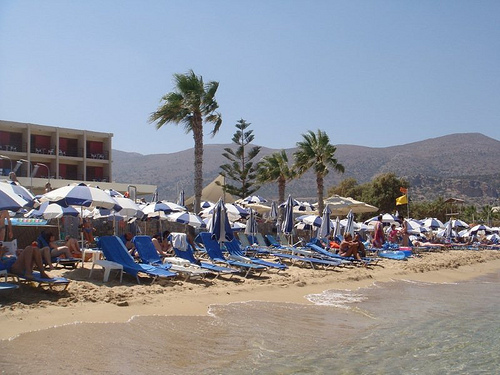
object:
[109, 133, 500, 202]
land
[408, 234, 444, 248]
person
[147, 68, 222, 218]
tree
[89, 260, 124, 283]
table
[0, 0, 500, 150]
blue sky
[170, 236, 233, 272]
towel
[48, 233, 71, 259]
person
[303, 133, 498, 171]
mountain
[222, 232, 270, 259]
chair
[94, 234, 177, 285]
beach chair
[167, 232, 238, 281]
beach chair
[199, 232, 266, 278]
beach chair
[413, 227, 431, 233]
umbrella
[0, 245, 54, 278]
person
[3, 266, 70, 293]
chair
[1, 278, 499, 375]
foam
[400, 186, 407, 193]
flag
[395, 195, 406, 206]
flag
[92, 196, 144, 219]
umbrellas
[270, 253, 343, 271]
beach chair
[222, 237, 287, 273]
beach chair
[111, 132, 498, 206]
mountain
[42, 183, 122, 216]
tent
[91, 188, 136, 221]
umbrellas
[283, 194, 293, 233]
umbrellas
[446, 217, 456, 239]
umbrellas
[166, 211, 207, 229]
umbrellas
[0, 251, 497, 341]
sand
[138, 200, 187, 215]
umbrella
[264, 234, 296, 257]
chairs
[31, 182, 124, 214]
parasol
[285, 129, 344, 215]
tree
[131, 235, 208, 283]
beach chair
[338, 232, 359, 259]
person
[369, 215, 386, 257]
person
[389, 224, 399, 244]
person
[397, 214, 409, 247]
person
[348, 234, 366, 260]
person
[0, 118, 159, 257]
building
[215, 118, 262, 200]
tree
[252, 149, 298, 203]
tree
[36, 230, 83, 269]
chair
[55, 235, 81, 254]
person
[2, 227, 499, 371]
beach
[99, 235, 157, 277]
towel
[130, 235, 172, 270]
towel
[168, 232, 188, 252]
towel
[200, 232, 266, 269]
towel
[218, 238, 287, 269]
towel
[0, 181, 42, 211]
umbrella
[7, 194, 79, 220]
umbrella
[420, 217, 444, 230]
umbrella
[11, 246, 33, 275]
leg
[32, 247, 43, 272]
leg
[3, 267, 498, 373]
water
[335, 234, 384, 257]
chairs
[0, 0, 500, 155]
clouds